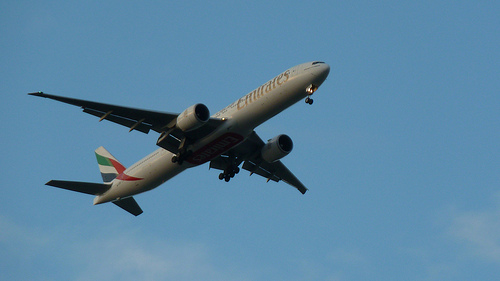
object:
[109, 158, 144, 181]
shape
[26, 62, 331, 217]
airplane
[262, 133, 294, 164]
engine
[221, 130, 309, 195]
left wing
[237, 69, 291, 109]
emirates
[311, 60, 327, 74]
cockpit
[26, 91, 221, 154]
wing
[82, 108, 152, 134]
flap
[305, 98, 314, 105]
wheels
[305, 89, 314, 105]
landing gear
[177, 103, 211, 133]
engine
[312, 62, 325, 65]
window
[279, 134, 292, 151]
holes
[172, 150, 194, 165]
wheels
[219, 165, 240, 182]
wheels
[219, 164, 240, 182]
landing gear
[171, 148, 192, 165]
landing gear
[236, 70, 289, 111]
lettering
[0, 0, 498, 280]
air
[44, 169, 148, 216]
tail